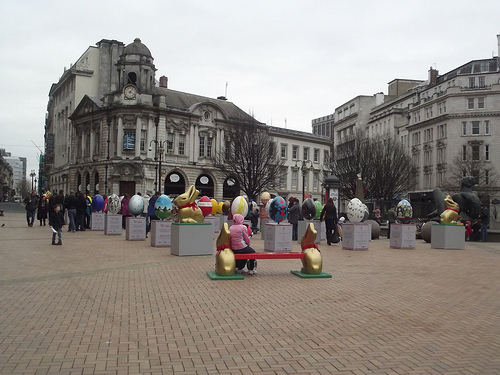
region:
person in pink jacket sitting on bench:
[221, 215, 325, 276]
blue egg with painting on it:
[154, 191, 175, 220]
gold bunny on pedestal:
[429, 195, 466, 229]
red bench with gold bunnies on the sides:
[200, 229, 331, 270]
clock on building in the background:
[122, 81, 143, 101]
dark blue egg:
[89, 195, 105, 212]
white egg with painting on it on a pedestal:
[346, 191, 370, 246]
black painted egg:
[296, 197, 318, 219]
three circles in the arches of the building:
[167, 167, 249, 191]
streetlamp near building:
[136, 130, 176, 190]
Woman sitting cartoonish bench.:
[184, 203, 343, 292]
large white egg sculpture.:
[335, 186, 384, 258]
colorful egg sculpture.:
[388, 182, 424, 259]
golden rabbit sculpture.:
[415, 178, 461, 265]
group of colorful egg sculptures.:
[53, 163, 291, 272]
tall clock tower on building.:
[103, 30, 178, 114]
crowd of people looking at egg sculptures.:
[2, 186, 137, 248]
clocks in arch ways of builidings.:
[155, 165, 251, 193]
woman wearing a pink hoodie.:
[218, 214, 269, 264]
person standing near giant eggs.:
[313, 196, 346, 255]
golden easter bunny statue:
[427, 190, 465, 251]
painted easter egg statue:
[385, 190, 415, 260]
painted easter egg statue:
[341, 195, 371, 251]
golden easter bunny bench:
[210, 215, 330, 285]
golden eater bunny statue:
[169, 185, 214, 266]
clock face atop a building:
[121, 80, 142, 105]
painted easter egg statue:
[126, 195, 147, 246]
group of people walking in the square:
[18, 185, 93, 247]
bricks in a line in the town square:
[56, 259, 127, 336]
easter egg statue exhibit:
[30, 165, 472, 263]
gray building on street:
[17, 21, 286, 204]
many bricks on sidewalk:
[179, 281, 318, 348]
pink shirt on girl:
[226, 211, 266, 263]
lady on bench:
[206, 218, 270, 266]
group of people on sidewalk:
[35, 178, 105, 235]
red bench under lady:
[221, 248, 309, 279]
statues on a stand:
[339, 188, 427, 240]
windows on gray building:
[179, 131, 224, 164]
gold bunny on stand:
[166, 178, 216, 236]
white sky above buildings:
[195, 6, 358, 117]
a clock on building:
[118, 65, 144, 101]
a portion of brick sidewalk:
[131, 310, 323, 359]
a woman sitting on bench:
[231, 216, 258, 271]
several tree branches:
[228, 128, 275, 185]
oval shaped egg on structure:
[392, 197, 422, 246]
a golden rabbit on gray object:
[175, 190, 203, 230]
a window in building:
[166, 170, 186, 190]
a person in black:
[320, 194, 345, 250]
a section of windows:
[454, 98, 496, 138]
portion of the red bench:
[260, 249, 299, 261]